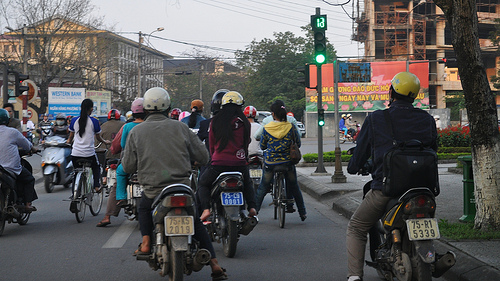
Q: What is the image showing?
A: It is showing a road.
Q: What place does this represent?
A: It represents the road.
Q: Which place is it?
A: It is a road.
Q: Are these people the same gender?
A: Yes, all the people are female.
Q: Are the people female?
A: Yes, all the people are female.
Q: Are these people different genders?
A: No, all the people are female.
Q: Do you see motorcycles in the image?
A: Yes, there is a motorcycle.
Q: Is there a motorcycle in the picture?
A: Yes, there is a motorcycle.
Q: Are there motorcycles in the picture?
A: Yes, there is a motorcycle.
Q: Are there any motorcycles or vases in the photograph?
A: Yes, there is a motorcycle.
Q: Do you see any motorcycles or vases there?
A: Yes, there is a motorcycle.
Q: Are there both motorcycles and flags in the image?
A: No, there is a motorcycle but no flags.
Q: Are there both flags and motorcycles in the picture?
A: No, there is a motorcycle but no flags.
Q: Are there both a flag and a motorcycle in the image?
A: No, there is a motorcycle but no flags.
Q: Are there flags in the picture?
A: No, there are no flags.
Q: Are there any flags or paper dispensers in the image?
A: No, there are no flags or paper dispensers.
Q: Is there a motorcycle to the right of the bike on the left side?
A: Yes, there is a motorcycle to the right of the bike.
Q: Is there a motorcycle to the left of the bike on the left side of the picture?
A: No, the motorcycle is to the right of the bike.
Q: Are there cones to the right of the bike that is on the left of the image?
A: No, there is a motorcycle to the right of the bike.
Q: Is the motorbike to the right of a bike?
A: Yes, the motorbike is to the right of a bike.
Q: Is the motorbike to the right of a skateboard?
A: No, the motorbike is to the right of a bike.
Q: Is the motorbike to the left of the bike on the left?
A: No, the motorbike is to the right of the bike.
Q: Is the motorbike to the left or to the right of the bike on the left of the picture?
A: The motorbike is to the right of the bike.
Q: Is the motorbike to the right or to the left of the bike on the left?
A: The motorbike is to the right of the bike.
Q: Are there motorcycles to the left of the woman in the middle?
A: Yes, there is a motorcycle to the left of the woman.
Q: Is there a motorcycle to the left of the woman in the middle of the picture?
A: Yes, there is a motorcycle to the left of the woman.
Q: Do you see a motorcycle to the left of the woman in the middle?
A: Yes, there is a motorcycle to the left of the woman.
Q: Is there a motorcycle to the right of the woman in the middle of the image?
A: No, the motorcycle is to the left of the woman.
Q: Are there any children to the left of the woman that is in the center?
A: No, there is a motorcycle to the left of the woman.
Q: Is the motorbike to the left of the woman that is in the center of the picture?
A: Yes, the motorbike is to the left of the woman.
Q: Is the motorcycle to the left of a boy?
A: No, the motorcycle is to the left of the woman.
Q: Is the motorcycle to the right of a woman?
A: No, the motorcycle is to the left of a woman.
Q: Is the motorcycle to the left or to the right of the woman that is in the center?
A: The motorcycle is to the left of the woman.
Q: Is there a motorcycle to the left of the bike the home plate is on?
A: Yes, there is a motorcycle to the left of the bike.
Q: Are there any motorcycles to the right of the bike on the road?
A: No, the motorcycle is to the left of the bike.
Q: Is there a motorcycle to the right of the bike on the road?
A: No, the motorcycle is to the left of the bike.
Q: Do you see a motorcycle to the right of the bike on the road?
A: No, the motorcycle is to the left of the bike.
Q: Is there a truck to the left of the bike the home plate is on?
A: No, there is a motorcycle to the left of the bike.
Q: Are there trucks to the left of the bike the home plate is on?
A: No, there is a motorcycle to the left of the bike.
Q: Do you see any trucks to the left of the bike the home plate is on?
A: No, there is a motorcycle to the left of the bike.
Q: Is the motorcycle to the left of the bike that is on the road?
A: Yes, the motorcycle is to the left of the bike.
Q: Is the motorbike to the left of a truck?
A: No, the motorbike is to the left of the bike.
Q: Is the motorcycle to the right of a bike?
A: No, the motorcycle is to the left of a bike.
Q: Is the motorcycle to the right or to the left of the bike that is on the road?
A: The motorcycle is to the left of the bike.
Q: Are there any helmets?
A: Yes, there is a helmet.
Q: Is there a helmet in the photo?
A: Yes, there is a helmet.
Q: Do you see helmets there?
A: Yes, there is a helmet.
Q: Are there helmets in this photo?
A: Yes, there is a helmet.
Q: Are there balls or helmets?
A: Yes, there is a helmet.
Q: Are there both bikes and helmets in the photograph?
A: Yes, there are both a helmet and a bike.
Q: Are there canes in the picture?
A: No, there are no canes.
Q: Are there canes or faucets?
A: No, there are no canes or faucets.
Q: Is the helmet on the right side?
A: Yes, the helmet is on the right of the image.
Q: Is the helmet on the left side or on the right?
A: The helmet is on the right of the image.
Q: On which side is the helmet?
A: The helmet is on the right of the image.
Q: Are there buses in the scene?
A: No, there are no buses.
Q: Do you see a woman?
A: Yes, there is a woman.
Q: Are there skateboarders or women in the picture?
A: Yes, there is a woman.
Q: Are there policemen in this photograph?
A: No, there are no policemen.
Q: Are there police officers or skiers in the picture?
A: No, there are no police officers or skiers.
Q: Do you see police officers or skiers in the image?
A: No, there are no police officers or skiers.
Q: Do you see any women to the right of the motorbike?
A: Yes, there is a woman to the right of the motorbike.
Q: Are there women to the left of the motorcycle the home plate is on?
A: No, the woman is to the right of the motorbike.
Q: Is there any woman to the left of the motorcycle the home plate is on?
A: No, the woman is to the right of the motorbike.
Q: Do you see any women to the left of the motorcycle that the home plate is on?
A: No, the woman is to the right of the motorbike.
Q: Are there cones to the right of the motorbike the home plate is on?
A: No, there is a woman to the right of the motorcycle.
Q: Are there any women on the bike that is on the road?
A: Yes, there is a woman on the bike.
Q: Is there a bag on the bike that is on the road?
A: No, there is a woman on the bike.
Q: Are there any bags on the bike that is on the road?
A: No, there is a woman on the bike.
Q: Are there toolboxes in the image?
A: No, there are no toolboxes.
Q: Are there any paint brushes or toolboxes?
A: No, there are no toolboxes or paint brushes.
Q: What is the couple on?
A: The couple is on the motorcycle.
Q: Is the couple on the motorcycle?
A: Yes, the couple is on the motorcycle.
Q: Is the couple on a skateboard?
A: No, the couple is on the motorcycle.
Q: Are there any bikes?
A: Yes, there is a bike.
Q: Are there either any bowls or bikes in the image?
A: Yes, there is a bike.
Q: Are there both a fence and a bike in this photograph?
A: No, there is a bike but no fences.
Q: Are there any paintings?
A: No, there are no paintings.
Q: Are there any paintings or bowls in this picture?
A: No, there are no paintings or bowls.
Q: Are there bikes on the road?
A: Yes, there is a bike on the road.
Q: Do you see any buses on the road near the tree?
A: No, there is a bike on the road.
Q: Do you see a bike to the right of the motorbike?
A: Yes, there is a bike to the right of the motorbike.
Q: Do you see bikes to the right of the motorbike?
A: Yes, there is a bike to the right of the motorbike.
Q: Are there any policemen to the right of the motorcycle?
A: No, there is a bike to the right of the motorcycle.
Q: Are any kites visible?
A: No, there are no kites.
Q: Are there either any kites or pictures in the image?
A: No, there are no kites or pictures.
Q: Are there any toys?
A: No, there are no toys.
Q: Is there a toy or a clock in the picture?
A: No, there are no toys or clocks.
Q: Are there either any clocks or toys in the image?
A: No, there are no toys or clocks.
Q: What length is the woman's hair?
A: The hair is long.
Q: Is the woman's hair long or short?
A: The hair is long.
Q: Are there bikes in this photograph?
A: Yes, there is a bike.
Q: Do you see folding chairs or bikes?
A: Yes, there is a bike.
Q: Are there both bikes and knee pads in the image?
A: No, there is a bike but no knee pads.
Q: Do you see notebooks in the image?
A: No, there are no notebooks.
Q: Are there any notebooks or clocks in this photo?
A: No, there are no notebooks or clocks.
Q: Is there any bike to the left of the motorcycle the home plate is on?
A: Yes, there is a bike to the left of the motorbike.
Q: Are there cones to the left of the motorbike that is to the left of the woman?
A: No, there is a bike to the left of the motorbike.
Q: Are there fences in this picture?
A: No, there are no fences.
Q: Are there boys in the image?
A: No, there are no boys.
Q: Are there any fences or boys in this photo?
A: No, there are no boys or fences.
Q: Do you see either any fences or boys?
A: No, there are no boys or fences.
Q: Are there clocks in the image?
A: No, there are no clocks.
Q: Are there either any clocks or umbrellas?
A: No, there are no clocks or umbrellas.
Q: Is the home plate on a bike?
A: Yes, the home plate is on a bike.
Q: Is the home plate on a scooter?
A: No, the home plate is on a bike.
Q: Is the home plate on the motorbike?
A: Yes, the home plate is on the motorbike.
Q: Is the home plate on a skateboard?
A: No, the home plate is on the motorbike.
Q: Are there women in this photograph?
A: Yes, there is a woman.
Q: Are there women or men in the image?
A: Yes, there is a woman.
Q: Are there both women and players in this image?
A: No, there is a woman but no players.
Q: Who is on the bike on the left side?
A: The woman is on the bike.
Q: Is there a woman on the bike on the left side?
A: Yes, there is a woman on the bike.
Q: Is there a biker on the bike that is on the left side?
A: No, there is a woman on the bike.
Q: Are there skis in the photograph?
A: No, there are no skis.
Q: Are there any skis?
A: No, there are no skis.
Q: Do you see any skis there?
A: No, there are no skis.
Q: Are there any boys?
A: No, there are no boys.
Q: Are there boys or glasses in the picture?
A: No, there are no boys or glasses.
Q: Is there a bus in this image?
A: No, there are no buses.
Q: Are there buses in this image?
A: No, there are no buses.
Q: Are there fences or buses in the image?
A: No, there are no buses or fences.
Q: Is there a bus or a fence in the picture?
A: No, there are no buses or fences.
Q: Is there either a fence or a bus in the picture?
A: No, there are no buses or fences.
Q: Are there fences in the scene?
A: No, there are no fences.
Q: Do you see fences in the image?
A: No, there are no fences.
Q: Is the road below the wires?
A: Yes, the road is below the wires.